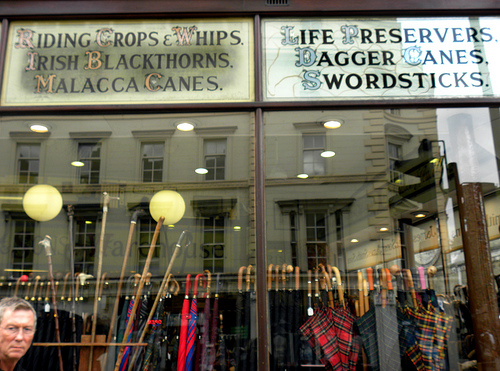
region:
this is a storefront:
[25, 13, 450, 343]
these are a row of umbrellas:
[66, 256, 481, 363]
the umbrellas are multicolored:
[139, 266, 474, 361]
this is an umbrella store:
[24, 243, 404, 368]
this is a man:
[2, 292, 47, 356]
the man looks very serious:
[1, 298, 45, 358]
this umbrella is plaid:
[292, 288, 360, 348]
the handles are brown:
[230, 258, 305, 283]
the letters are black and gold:
[14, 18, 236, 108]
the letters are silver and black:
[272, 31, 462, 88]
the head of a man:
[0, 295, 36, 370]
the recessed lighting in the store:
[29, 120, 437, 252]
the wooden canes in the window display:
[37, 189, 192, 369]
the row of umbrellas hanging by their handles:
[0, 262, 452, 369]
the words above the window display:
[12, 22, 498, 96]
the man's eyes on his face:
[7, 324, 31, 333]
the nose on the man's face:
[14, 327, 24, 342]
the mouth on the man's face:
[10, 344, 22, 349]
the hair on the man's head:
[2, 295, 37, 329]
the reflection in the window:
[0, 111, 498, 370]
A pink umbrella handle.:
[415, 263, 428, 288]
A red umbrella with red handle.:
[176, 268, 191, 366]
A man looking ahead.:
[0, 292, 40, 368]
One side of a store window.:
[260, 105, 498, 370]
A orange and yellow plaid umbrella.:
[400, 265, 451, 368]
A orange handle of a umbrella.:
[381, 263, 392, 288]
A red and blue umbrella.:
[181, 267, 206, 367]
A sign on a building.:
[257, 10, 497, 105]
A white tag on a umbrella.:
[305, 305, 315, 316]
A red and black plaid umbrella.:
[299, 259, 360, 369]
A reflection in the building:
[5, 113, 494, 369]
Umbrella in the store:
[6, 243, 465, 369]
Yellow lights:
[15, 165, 196, 243]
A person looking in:
[3, 297, 46, 369]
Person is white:
[3, 296, 67, 368]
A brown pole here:
[242, 108, 307, 369]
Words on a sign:
[54, 208, 271, 285]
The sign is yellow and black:
[29, 207, 276, 288]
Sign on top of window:
[5, 13, 497, 108]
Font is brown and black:
[10, 17, 246, 98]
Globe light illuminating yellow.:
[146, 189, 185, 224]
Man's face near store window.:
[0, 290, 40, 369]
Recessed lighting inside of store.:
[297, 116, 339, 195]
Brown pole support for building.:
[448, 117, 498, 369]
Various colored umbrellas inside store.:
[270, 267, 452, 364]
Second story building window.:
[280, 196, 357, 278]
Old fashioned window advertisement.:
[14, 26, 251, 93]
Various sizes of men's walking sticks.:
[37, 190, 192, 369]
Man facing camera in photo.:
[2, 294, 35, 365]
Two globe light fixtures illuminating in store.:
[20, 182, 185, 229]